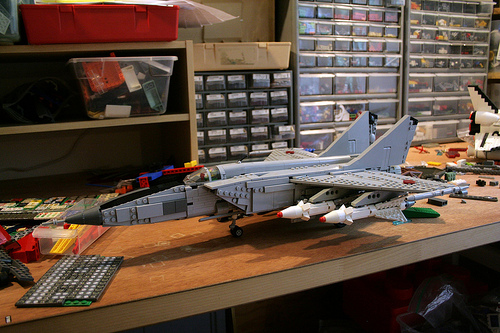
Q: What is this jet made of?
A: Legos.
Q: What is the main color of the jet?
A: Grey.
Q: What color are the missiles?
A: White.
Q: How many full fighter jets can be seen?
A: One.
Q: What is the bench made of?
A: Wood.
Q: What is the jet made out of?
A: Legos.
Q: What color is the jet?
A: Grey.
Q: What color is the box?
A: Transparent.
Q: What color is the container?
A: Red.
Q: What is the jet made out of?
A: Legos.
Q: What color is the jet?
A: Grey.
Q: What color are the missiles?
A: White.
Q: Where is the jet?
A: On the workbench.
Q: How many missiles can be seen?
A: Two.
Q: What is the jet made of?
A: Legos.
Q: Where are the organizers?
A: At the back of the bench.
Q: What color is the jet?
A: Gray.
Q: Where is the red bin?
A: On the top shelf.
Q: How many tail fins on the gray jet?
A: Two.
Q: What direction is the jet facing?
A: To the left.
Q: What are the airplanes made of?
A: Legos.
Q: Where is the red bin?
A: On the shelf.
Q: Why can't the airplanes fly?
A: Models.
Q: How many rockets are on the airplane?
A: 2.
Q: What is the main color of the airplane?
A: Gray.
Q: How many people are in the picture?
A: 0.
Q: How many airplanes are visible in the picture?
A: 2.